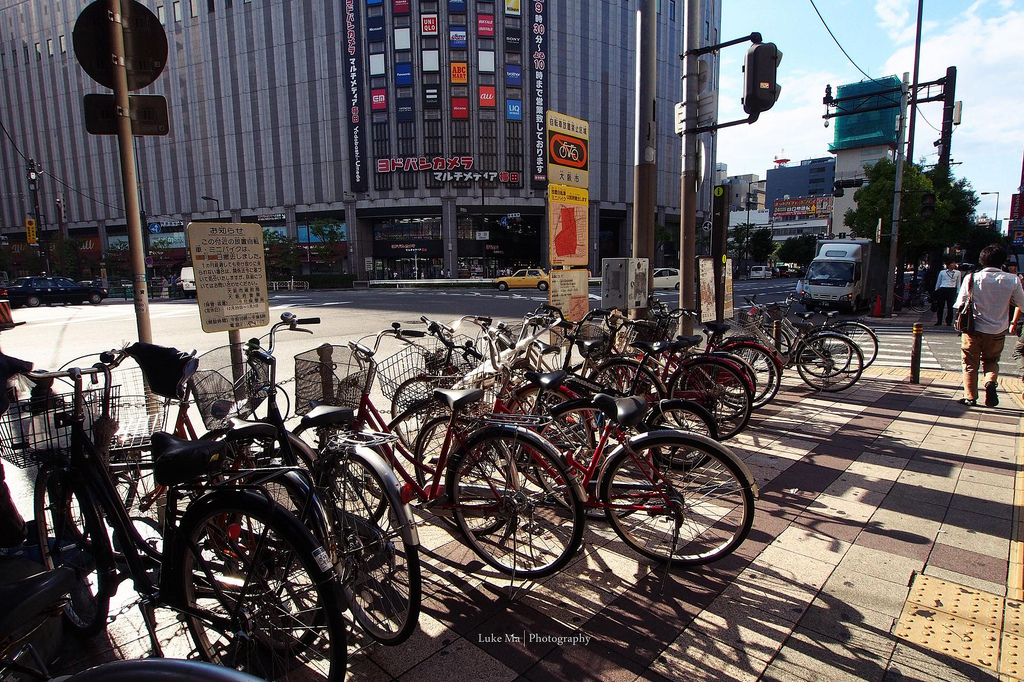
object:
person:
[950, 246, 1019, 408]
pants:
[961, 331, 1005, 402]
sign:
[187, 221, 268, 334]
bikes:
[0, 296, 877, 677]